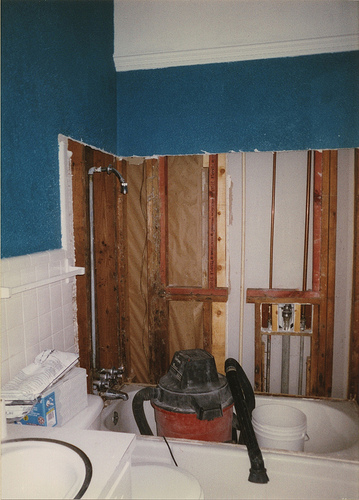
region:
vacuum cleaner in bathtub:
[130, 326, 287, 495]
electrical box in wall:
[251, 292, 331, 343]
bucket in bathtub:
[248, 391, 319, 464]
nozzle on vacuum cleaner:
[227, 401, 276, 489]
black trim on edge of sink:
[56, 434, 99, 486]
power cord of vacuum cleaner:
[151, 407, 184, 468]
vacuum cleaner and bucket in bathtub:
[132, 342, 320, 460]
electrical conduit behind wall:
[275, 337, 303, 391]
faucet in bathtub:
[88, 362, 153, 422]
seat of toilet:
[132, 445, 225, 498]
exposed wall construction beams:
[56, 131, 337, 401]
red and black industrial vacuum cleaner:
[131, 344, 270, 483]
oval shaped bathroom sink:
[1, 434, 94, 498]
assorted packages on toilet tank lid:
[0, 345, 106, 428]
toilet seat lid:
[127, 460, 199, 494]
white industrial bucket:
[249, 400, 311, 450]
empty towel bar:
[0, 256, 86, 299]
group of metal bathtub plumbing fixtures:
[90, 358, 128, 404]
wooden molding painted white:
[113, 33, 358, 74]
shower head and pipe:
[86, 163, 118, 378]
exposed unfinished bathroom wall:
[23, 107, 357, 393]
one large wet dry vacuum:
[123, 345, 269, 489]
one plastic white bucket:
[252, 401, 313, 454]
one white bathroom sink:
[1, 416, 139, 499]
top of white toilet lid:
[132, 456, 204, 498]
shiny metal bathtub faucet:
[91, 362, 131, 406]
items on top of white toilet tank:
[10, 351, 103, 427]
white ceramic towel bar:
[1, 255, 86, 301]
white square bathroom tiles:
[6, 261, 72, 348]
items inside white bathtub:
[104, 381, 357, 467]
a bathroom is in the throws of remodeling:
[9, 99, 357, 498]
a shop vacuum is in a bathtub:
[128, 345, 277, 485]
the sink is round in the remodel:
[1, 423, 132, 494]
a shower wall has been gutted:
[66, 140, 350, 404]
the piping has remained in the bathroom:
[83, 162, 314, 392]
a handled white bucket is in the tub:
[252, 400, 313, 454]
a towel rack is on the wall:
[1, 264, 88, 301]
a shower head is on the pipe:
[116, 179, 131, 199]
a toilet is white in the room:
[58, 392, 206, 499]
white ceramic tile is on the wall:
[0, 247, 85, 424]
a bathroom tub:
[64, 282, 356, 493]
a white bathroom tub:
[79, 305, 297, 489]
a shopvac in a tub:
[93, 323, 322, 468]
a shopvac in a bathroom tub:
[133, 322, 318, 477]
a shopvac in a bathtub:
[74, 296, 278, 496]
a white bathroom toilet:
[18, 326, 267, 498]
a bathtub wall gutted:
[76, 133, 357, 375]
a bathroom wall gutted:
[43, 124, 312, 393]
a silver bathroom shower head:
[54, 132, 190, 414]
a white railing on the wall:
[4, 226, 148, 335]